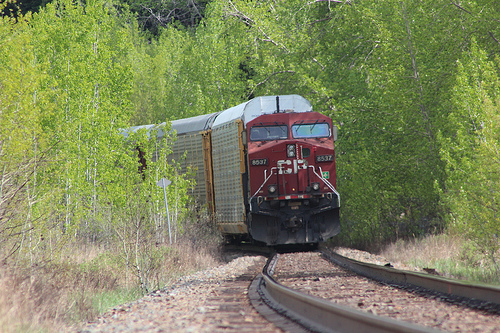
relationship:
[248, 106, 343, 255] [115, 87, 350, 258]
front of train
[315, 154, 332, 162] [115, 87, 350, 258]
number on train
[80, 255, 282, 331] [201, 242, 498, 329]
rocks next to track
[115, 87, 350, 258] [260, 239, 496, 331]
train traveling down tracks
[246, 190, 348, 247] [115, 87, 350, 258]
metal plate on train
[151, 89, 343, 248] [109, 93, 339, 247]
cars of train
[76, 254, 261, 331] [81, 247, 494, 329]
pebbles on ground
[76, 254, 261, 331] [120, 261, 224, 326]
pebbles on ground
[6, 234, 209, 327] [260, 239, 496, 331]
grass near tracks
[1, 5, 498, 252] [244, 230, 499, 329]
trees around track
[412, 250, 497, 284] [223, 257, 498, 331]
grass near track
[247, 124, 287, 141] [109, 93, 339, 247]
window of train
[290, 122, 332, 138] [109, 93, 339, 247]
window of train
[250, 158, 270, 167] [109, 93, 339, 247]
numbers on train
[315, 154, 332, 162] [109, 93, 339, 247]
number on train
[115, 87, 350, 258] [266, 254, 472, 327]
train on tracks